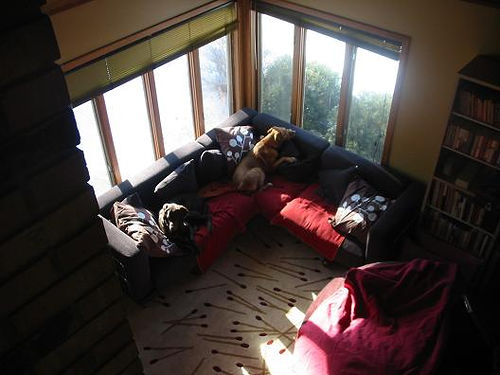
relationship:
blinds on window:
[246, 0, 413, 66] [244, 5, 406, 175]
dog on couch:
[148, 180, 231, 260] [84, 104, 420, 292]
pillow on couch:
[332, 178, 397, 238] [86, 105, 406, 275]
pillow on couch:
[213, 125, 263, 167] [86, 105, 406, 275]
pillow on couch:
[110, 191, 173, 254] [86, 105, 406, 275]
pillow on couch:
[151, 160, 198, 202] [86, 105, 406, 275]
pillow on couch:
[110, 191, 173, 254] [82, 106, 437, 313]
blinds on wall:
[246, 0, 414, 165] [241, 9, 466, 225]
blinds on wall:
[67, 35, 238, 203] [49, 3, 242, 104]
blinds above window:
[65, 1, 238, 83] [67, 29, 243, 195]